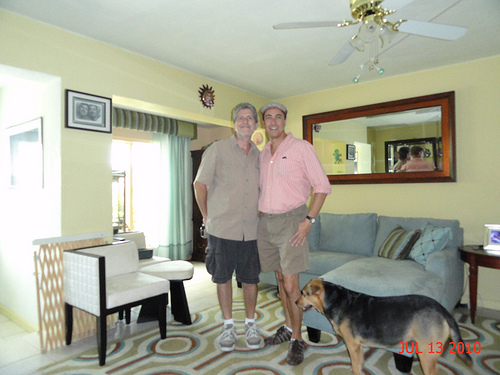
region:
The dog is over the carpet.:
[295, 280, 471, 374]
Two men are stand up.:
[194, 103, 332, 363]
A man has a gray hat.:
[261, 101, 286, 139]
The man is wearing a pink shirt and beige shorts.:
[261, 102, 332, 367]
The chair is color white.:
[61, 240, 194, 367]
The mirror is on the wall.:
[303, 95, 455, 182]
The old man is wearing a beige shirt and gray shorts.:
[193, 101, 270, 349]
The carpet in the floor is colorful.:
[36, 285, 496, 373]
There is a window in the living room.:
[111, 132, 172, 260]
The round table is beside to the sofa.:
[458, 242, 498, 322]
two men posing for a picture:
[191, 100, 327, 362]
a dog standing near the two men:
[295, 275, 474, 372]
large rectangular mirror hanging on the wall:
[300, 92, 462, 185]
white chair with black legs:
[57, 237, 169, 366]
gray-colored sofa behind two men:
[226, 209, 466, 354]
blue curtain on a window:
[155, 128, 194, 258]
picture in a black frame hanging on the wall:
[65, 87, 115, 134]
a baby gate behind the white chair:
[31, 230, 115, 350]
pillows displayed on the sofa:
[378, 221, 451, 266]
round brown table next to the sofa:
[455, 242, 499, 323]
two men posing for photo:
[184, 96, 320, 367]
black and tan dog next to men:
[285, 273, 458, 366]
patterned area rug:
[82, 280, 497, 374]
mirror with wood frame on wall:
[298, 95, 459, 200]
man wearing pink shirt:
[260, 107, 310, 362]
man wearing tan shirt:
[196, 101, 277, 333]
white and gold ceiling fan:
[274, 1, 459, 77]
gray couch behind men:
[245, 198, 452, 315]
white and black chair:
[76, 239, 193, 351]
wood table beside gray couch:
[462, 226, 499, 325]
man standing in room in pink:
[274, 106, 356, 338]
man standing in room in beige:
[192, 89, 261, 292]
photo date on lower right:
[374, 340, 499, 365]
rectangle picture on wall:
[62, 91, 133, 141]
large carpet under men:
[83, 283, 338, 365]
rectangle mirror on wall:
[292, 102, 464, 192]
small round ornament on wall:
[194, 77, 231, 117]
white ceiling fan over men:
[282, 5, 490, 65]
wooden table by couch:
[466, 235, 493, 289]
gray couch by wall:
[271, 205, 498, 310]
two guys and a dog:
[58, 53, 470, 360]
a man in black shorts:
[190, 96, 265, 358]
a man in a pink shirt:
[256, 106, 327, 358]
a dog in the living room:
[286, 257, 482, 374]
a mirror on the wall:
[298, 106, 474, 193]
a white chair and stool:
[50, 241, 197, 346]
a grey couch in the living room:
[316, 196, 458, 298]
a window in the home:
[101, 108, 191, 259]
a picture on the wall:
[49, 83, 119, 135]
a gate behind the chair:
[20, 234, 93, 353]